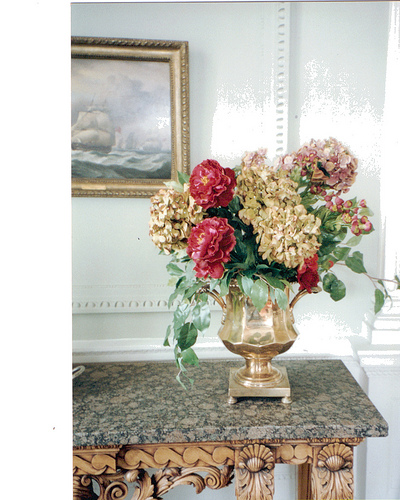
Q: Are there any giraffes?
A: No, there are no giraffes.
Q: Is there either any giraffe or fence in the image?
A: No, there are no giraffes or fences.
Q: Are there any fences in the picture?
A: No, there are no fences.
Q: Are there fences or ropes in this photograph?
A: No, there are no fences or ropes.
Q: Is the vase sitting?
A: Yes, the vase is sitting.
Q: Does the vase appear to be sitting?
A: Yes, the vase is sitting.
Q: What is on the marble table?
A: The vase is on the table.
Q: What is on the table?
A: The vase is on the table.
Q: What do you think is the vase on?
A: The vase is on the table.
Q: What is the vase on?
A: The vase is on the table.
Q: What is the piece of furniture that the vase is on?
A: The piece of furniture is a table.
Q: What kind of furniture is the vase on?
A: The vase is on the table.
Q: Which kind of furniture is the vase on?
A: The vase is on the table.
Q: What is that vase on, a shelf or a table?
A: The vase is on a table.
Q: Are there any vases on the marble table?
A: Yes, there is a vase on the table.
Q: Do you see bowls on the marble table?
A: No, there is a vase on the table.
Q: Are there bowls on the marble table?
A: No, there is a vase on the table.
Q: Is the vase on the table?
A: Yes, the vase is on the table.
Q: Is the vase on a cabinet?
A: No, the vase is on the table.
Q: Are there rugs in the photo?
A: No, there are no rugs.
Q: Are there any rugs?
A: No, there are no rugs.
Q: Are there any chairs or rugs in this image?
A: No, there are no rugs or chairs.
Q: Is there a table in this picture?
A: Yes, there is a table.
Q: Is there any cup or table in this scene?
A: Yes, there is a table.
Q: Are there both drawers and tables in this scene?
A: No, there is a table but no drawers.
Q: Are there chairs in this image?
A: No, there are no chairs.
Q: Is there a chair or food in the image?
A: No, there are no chairs or food.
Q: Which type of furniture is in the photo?
A: The furniture is a table.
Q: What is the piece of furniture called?
A: The piece of furniture is a table.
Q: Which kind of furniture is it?
A: The piece of furniture is a table.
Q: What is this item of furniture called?
A: This is a table.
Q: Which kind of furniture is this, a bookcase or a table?
A: This is a table.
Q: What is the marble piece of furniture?
A: The piece of furniture is a table.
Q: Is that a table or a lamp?
A: That is a table.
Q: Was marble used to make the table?
A: Yes, the table is made of marble.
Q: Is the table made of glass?
A: No, the table is made of marble.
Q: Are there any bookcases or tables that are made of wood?
A: No, there is a table but it is made of marble.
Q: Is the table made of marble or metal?
A: The table is made of marble.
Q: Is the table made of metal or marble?
A: The table is made of marble.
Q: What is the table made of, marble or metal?
A: The table is made of marble.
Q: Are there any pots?
A: No, there are no pots.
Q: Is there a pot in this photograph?
A: No, there are no pots.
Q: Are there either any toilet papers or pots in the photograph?
A: No, there are no pots or toilet papers.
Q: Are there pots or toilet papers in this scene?
A: No, there are no pots or toilet papers.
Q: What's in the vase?
A: The flowers are in the vase.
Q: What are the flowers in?
A: The flowers are in the vase.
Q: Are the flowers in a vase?
A: Yes, the flowers are in a vase.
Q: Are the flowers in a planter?
A: No, the flowers are in a vase.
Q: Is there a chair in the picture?
A: No, there are no chairs.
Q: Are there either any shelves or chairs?
A: No, there are no chairs or shelves.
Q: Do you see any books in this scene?
A: No, there are no books.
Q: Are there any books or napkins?
A: No, there are no books or napkins.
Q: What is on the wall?
A: The picture is on the wall.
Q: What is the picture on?
A: The picture is on the wall.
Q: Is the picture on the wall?
A: Yes, the picture is on the wall.